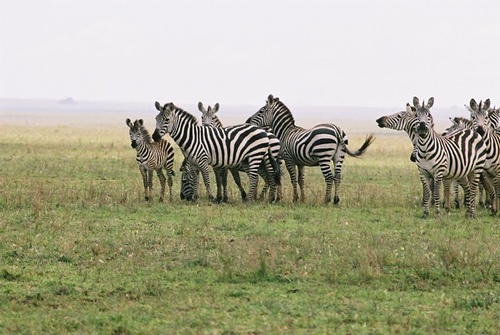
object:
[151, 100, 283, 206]
zebra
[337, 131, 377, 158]
tail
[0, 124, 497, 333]
on grass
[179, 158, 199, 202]
zebra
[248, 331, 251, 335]
away camera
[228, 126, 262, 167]
stripes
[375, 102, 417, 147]
zebra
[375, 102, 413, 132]
head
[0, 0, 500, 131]
air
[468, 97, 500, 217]
zebra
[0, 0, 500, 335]
in the air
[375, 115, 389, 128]
pointed nose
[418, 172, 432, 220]
legs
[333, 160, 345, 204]
legs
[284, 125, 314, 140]
back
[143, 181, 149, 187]
knobby knees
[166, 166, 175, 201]
skinny hind legs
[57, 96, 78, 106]
something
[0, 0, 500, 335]
sky+ground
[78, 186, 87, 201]
weeds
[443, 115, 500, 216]
zebra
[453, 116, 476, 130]
mane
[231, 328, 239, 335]
photographer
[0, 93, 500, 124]
hills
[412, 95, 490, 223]
zebra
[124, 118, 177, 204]
zebra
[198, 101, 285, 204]
zebra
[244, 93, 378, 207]
zebra